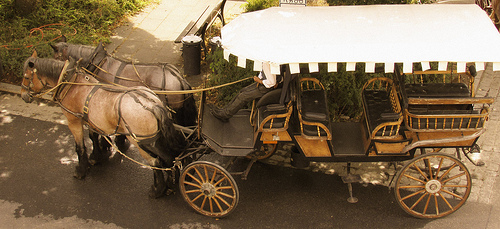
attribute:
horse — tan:
[18, 50, 185, 200]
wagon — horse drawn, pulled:
[178, 2, 499, 222]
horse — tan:
[48, 35, 201, 132]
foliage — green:
[3, 3, 153, 90]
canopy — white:
[219, 4, 500, 74]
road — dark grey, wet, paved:
[0, 89, 499, 227]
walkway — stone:
[396, 50, 499, 207]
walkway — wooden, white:
[99, 0, 243, 144]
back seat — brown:
[400, 70, 474, 104]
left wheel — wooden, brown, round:
[176, 160, 241, 218]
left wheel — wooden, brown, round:
[391, 151, 473, 222]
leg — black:
[70, 120, 90, 181]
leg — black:
[85, 127, 104, 167]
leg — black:
[151, 155, 168, 202]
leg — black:
[163, 164, 177, 196]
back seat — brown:
[402, 104, 489, 135]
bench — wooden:
[174, 0, 227, 52]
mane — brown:
[22, 55, 77, 82]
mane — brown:
[57, 42, 102, 63]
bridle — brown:
[19, 52, 49, 98]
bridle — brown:
[55, 44, 69, 61]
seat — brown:
[363, 87, 396, 135]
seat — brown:
[300, 89, 328, 135]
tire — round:
[178, 159, 241, 222]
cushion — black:
[303, 88, 329, 121]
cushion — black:
[362, 88, 395, 136]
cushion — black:
[402, 79, 471, 99]